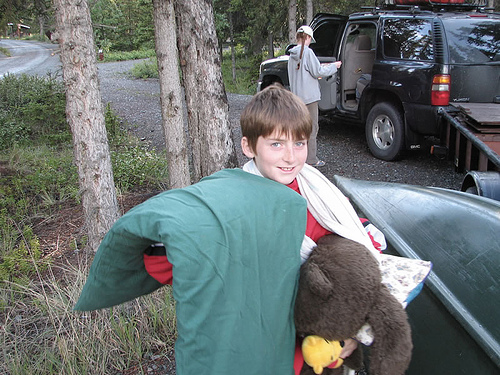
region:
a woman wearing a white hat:
[272, 22, 333, 84]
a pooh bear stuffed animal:
[291, 325, 363, 372]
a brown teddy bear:
[264, 195, 436, 370]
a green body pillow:
[59, 168, 319, 370]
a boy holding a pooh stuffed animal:
[151, 93, 431, 373]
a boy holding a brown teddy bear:
[211, 69, 448, 368]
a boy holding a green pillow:
[74, 88, 326, 373]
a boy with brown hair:
[220, 95, 325, 197]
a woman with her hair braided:
[273, 24, 346, 78]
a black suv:
[261, 3, 497, 145]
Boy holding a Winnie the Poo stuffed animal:
[291, 330, 384, 372]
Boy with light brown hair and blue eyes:
[235, 88, 320, 193]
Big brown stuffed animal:
[294, 232, 411, 374]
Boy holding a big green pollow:
[75, 168, 304, 373]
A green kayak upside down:
[326, 171, 498, 373]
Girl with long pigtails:
[289, 24, 315, 76]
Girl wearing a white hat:
[291, 23, 318, 53]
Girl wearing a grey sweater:
[284, 42, 338, 104]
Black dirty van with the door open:
[262, 12, 496, 151]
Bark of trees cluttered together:
[37, 2, 241, 189]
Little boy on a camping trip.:
[192, 71, 462, 357]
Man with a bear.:
[271, 183, 426, 368]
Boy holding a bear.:
[210, 108, 387, 370]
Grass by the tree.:
[18, 193, 142, 367]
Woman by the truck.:
[260, 9, 376, 162]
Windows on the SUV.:
[429, 62, 476, 121]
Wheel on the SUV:
[350, 84, 422, 213]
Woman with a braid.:
[276, 21, 366, 97]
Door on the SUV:
[286, 8, 424, 128]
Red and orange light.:
[386, 42, 471, 119]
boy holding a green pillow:
[72, 169, 269, 373]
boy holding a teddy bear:
[290, 216, 431, 372]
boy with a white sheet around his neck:
[216, 125, 381, 262]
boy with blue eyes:
[268, 132, 305, 154]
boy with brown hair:
[235, 73, 312, 153]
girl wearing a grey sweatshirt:
[286, 50, 332, 98]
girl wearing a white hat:
[293, 23, 321, 45]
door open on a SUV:
[306, 13, 383, 125]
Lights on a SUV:
[431, 70, 451, 111]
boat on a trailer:
[332, 155, 465, 303]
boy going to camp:
[137, 87, 405, 364]